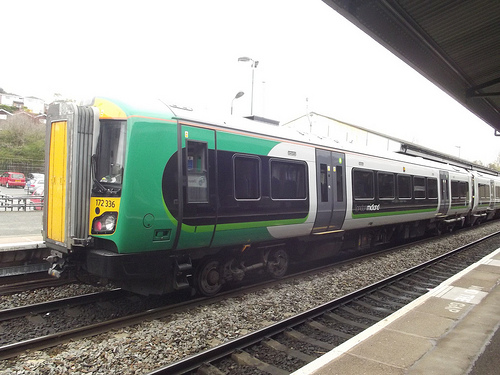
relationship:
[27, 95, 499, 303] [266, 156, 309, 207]
train has windows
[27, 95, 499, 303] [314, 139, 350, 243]
train has doors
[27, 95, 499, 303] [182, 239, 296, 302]
train has wheels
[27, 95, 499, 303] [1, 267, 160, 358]
train on top of rails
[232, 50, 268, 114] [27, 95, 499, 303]
lamp post behind train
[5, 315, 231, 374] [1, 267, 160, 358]
gravel beside rails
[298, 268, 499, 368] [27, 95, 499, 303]
loading ramp beside train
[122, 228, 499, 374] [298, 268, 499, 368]
second rails are beside loading ramp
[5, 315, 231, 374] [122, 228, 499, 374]
gravel beside second rails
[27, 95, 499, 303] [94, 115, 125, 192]
train has windows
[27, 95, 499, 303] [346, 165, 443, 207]
train has windows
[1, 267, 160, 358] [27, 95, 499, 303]
rails are beneath train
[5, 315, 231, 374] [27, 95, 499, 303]
gravel beneath train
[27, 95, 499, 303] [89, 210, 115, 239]
train has headlight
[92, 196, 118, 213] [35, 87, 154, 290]
numbers are on train front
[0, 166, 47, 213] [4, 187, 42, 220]
cars are in parking lot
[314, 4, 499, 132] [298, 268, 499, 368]
roof above loading ramp